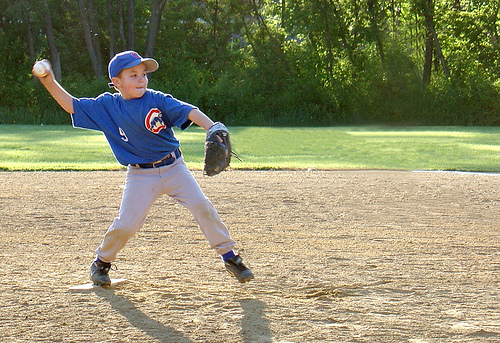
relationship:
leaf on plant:
[341, 73, 347, 78] [423, 42, 498, 124]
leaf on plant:
[364, 91, 367, 96] [378, 38, 423, 127]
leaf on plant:
[210, 80, 213, 82] [329, 40, 385, 123]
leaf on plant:
[261, 97, 265, 102] [271, 41, 338, 126]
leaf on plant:
[333, 94, 337, 101] [205, 58, 275, 125]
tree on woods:
[141, 0, 167, 77] [0, 2, 499, 127]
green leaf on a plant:
[437, 90, 448, 97] [381, 44, 499, 125]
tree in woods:
[141, 0, 168, 58] [0, 2, 499, 127]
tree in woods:
[317, 0, 345, 80] [0, 2, 499, 127]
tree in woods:
[310, 5, 363, 97] [0, 2, 499, 127]